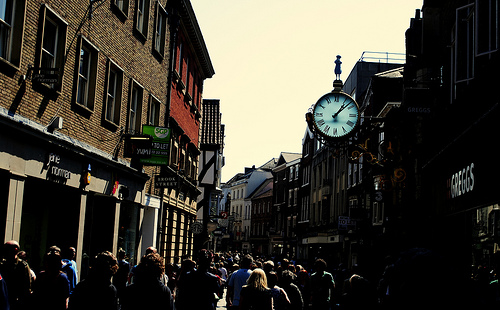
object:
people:
[170, 247, 225, 308]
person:
[237, 267, 274, 308]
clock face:
[311, 89, 360, 139]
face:
[311, 92, 362, 139]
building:
[155, 2, 215, 273]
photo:
[0, 0, 500, 308]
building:
[246, 157, 276, 248]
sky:
[188, 0, 423, 184]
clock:
[305, 53, 370, 150]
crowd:
[1, 248, 403, 308]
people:
[0, 240, 35, 306]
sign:
[137, 122, 174, 167]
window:
[305, 53, 367, 149]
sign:
[447, 162, 477, 200]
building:
[404, 0, 500, 257]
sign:
[157, 172, 179, 187]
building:
[1, 0, 173, 286]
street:
[0, 247, 500, 309]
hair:
[245, 266, 273, 294]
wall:
[163, 25, 203, 184]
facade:
[249, 198, 275, 258]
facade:
[301, 130, 367, 271]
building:
[301, 47, 409, 279]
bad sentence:
[309, 132, 327, 152]